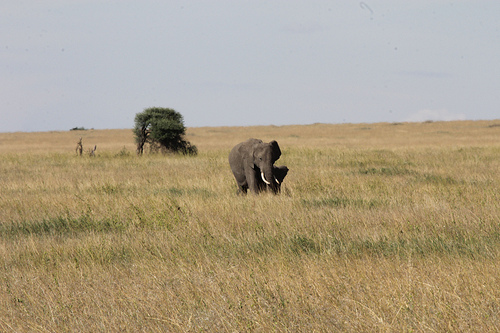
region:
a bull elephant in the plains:
[226, 136, 282, 195]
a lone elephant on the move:
[222, 135, 282, 196]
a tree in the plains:
[132, 107, 184, 159]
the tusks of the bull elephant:
[259, 170, 280, 186]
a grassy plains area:
[0, 120, 496, 330]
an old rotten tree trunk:
[75, 136, 82, 155]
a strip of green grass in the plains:
[4, 221, 497, 270]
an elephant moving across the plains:
[227, 133, 287, 200]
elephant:
[215, 132, 287, 193]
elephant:
[141, 101, 189, 162]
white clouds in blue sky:
[32, 21, 82, 58]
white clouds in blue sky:
[407, 39, 461, 101]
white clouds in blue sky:
[154, 45, 219, 92]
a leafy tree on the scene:
[133, 108, 193, 154]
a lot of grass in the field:
[12, 200, 394, 318]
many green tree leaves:
[149, 120, 181, 134]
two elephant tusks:
[259, 172, 280, 185]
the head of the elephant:
[252, 140, 278, 166]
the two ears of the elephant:
[249, 142, 281, 159]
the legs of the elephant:
[235, 173, 277, 193]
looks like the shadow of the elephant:
[272, 165, 288, 191]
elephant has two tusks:
[256, 169, 283, 188]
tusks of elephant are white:
[256, 167, 280, 190]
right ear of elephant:
[268, 137, 282, 162]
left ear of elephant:
[243, 142, 257, 169]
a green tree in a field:
[97, 103, 215, 165]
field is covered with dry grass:
[0, 128, 492, 329]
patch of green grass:
[1, 202, 137, 241]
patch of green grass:
[293, 223, 490, 261]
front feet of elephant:
[243, 167, 259, 193]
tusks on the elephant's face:
[244, 158, 285, 198]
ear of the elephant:
[263, 136, 290, 161]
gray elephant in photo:
[207, 118, 296, 200]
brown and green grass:
[313, 129, 440, 241]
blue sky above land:
[169, 8, 337, 72]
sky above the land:
[157, 18, 318, 100]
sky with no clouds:
[136, 4, 350, 79]